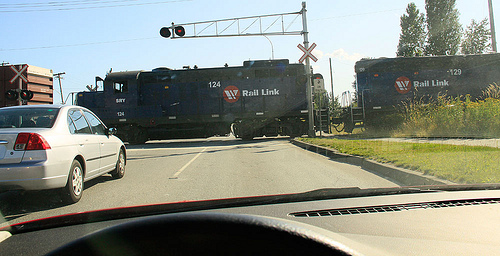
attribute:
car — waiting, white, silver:
[1, 101, 127, 203]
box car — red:
[0, 61, 55, 106]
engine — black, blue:
[74, 58, 331, 143]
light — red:
[174, 25, 185, 36]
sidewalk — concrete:
[317, 133, 499, 150]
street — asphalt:
[1, 142, 414, 228]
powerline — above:
[0, 1, 162, 11]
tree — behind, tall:
[395, 1, 428, 56]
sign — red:
[296, 41, 320, 68]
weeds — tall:
[397, 84, 499, 137]